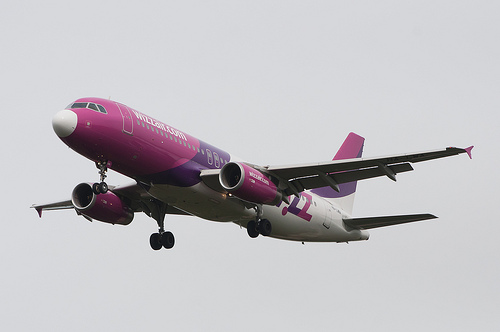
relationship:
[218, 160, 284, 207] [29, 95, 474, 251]
turbine engine under plane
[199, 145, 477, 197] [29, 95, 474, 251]
wing attached to plane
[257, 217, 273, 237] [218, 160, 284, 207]
black wheel under engine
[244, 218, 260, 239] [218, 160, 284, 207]
black wheel under engine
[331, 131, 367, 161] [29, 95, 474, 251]
tail of a plane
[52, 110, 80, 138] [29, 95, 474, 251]
nose of a plane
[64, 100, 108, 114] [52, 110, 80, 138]
windshield above nose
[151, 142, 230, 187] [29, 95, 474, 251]
stripe on plane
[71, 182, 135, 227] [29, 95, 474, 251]
engine of a plane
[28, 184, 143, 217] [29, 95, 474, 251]
wing of a plane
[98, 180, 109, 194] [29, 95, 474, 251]
wheel of plane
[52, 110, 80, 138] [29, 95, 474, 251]
nose of plane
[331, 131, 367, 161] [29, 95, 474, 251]
tail of plane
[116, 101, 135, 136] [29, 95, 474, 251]
door of plane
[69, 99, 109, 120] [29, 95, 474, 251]
cockpit of plane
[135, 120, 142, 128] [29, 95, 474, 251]
window on side of plane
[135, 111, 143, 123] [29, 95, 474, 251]
letter on side of plane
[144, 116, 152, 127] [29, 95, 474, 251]
letter on side of plane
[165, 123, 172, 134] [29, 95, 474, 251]
letter on side of plane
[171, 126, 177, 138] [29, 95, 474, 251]
letter on side of plane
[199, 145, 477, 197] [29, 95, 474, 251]
wing of a plane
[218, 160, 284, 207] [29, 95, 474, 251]
engine of a plane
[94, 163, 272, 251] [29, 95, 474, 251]
landing gear of a plane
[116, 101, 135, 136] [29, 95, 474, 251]
door of a plane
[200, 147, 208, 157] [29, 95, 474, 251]
window on side of plane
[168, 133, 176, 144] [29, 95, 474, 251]
window on side of plane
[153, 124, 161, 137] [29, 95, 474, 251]
window on side of plane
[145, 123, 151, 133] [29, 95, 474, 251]
window on side of plane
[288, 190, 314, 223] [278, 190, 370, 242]
letter p on tail